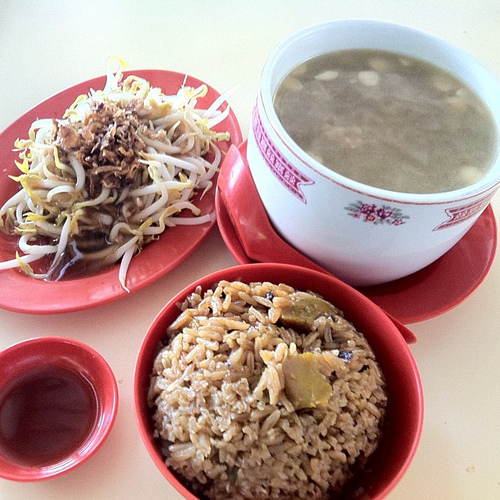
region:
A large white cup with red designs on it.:
[243, 20, 498, 284]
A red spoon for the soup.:
[216, 141, 433, 351]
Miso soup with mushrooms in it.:
[256, 37, 498, 208]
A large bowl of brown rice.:
[135, 256, 429, 498]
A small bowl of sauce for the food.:
[0, 333, 129, 485]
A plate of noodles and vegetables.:
[12, 80, 232, 260]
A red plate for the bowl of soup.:
[216, 126, 496, 323]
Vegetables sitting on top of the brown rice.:
[237, 284, 358, 421]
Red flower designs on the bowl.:
[342, 194, 411, 234]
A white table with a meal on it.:
[0, 0, 497, 499]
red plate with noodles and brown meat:
[14, 52, 216, 282]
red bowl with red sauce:
[9, 335, 122, 480]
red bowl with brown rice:
[153, 250, 455, 498]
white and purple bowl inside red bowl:
[226, 28, 476, 270]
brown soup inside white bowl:
[280, 53, 492, 205]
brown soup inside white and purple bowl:
[271, 55, 484, 215]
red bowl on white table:
[11, 326, 133, 488]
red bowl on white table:
[141, 259, 411, 499]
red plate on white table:
[13, 50, 228, 312]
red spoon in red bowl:
[201, 152, 296, 279]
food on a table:
[14, 20, 494, 497]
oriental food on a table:
[12, 14, 489, 486]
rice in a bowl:
[147, 248, 457, 497]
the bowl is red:
[140, 265, 452, 496]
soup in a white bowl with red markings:
[245, 15, 498, 268]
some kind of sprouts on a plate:
[19, 52, 241, 316]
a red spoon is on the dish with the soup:
[226, 18, 497, 325]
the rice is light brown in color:
[140, 288, 471, 495]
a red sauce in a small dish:
[7, 335, 130, 482]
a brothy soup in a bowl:
[252, 9, 497, 286]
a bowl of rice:
[166, 267, 409, 499]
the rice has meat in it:
[266, 299, 358, 419]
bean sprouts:
[26, 40, 197, 281]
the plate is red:
[18, 66, 216, 330]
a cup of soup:
[238, 15, 493, 254]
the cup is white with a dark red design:
[253, 107, 325, 222]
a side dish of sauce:
[6, 334, 122, 496]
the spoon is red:
[210, 137, 479, 357]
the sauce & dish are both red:
[6, 329, 126, 481]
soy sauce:
[0, 331, 123, 475]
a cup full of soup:
[253, 37, 498, 284]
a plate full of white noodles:
[0, 83, 255, 295]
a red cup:
[2, 321, 124, 478]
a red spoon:
[200, 141, 425, 356]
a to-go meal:
[17, 48, 489, 483]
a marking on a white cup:
[323, 194, 408, 227]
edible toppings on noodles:
[45, 82, 175, 218]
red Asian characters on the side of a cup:
[242, 67, 309, 207]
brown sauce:
[0, 335, 108, 472]